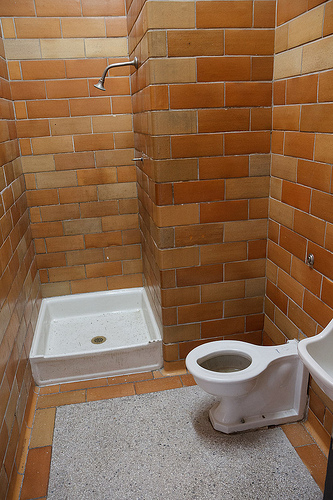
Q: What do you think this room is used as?
A: Washroom.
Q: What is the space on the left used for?
A: Showering.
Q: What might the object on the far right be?
A: Sink.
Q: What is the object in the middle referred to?
A: Toilet.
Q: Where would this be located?
A: Inside a home.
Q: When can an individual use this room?
A: As needed.